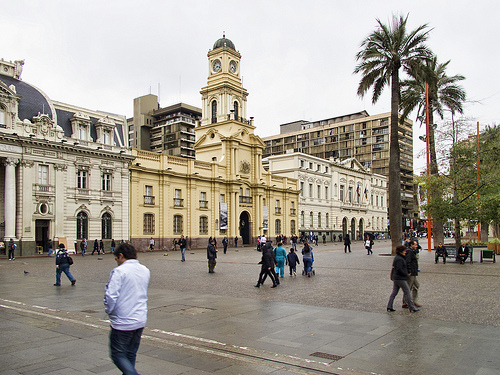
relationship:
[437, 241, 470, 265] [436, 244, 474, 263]
people on bench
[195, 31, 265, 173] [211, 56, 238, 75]
tower has clock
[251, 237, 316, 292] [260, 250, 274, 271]
people wearing jacket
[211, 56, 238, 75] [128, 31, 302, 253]
clock on building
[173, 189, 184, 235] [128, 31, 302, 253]
window on building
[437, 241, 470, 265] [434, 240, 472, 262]
people sitting on bench